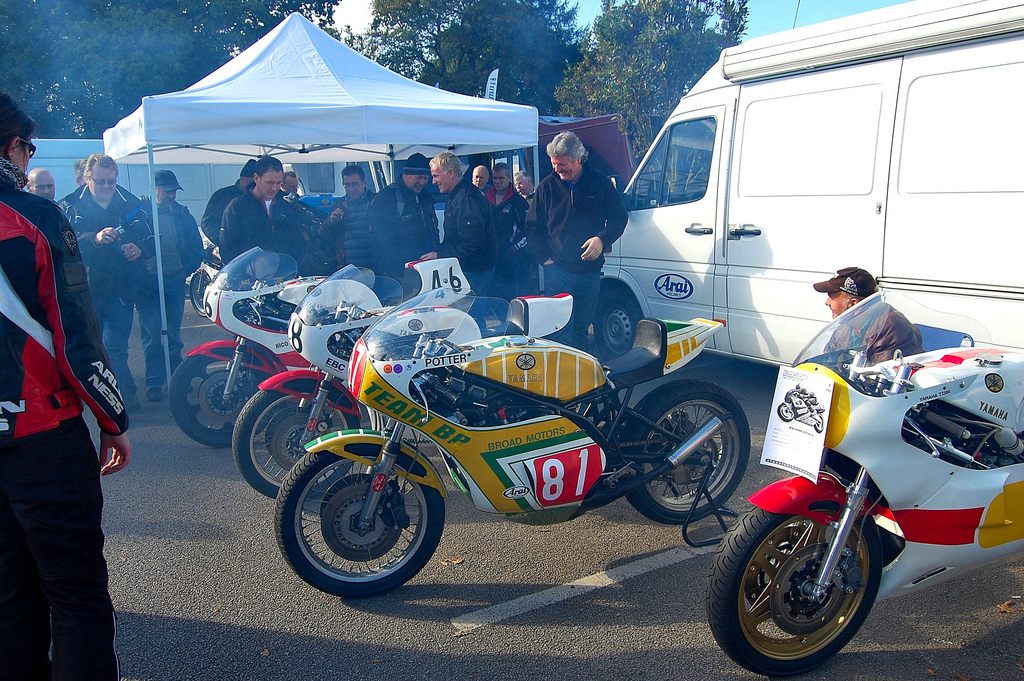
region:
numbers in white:
[541, 454, 595, 500]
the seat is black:
[616, 324, 655, 376]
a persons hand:
[88, 425, 139, 476]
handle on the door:
[685, 222, 709, 242]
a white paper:
[768, 371, 826, 471]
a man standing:
[423, 153, 488, 246]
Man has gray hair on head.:
[541, 127, 587, 167]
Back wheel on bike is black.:
[629, 376, 744, 514]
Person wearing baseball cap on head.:
[814, 265, 873, 308]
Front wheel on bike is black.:
[710, 492, 876, 664]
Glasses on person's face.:
[5, 135, 44, 158]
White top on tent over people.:
[106, 75, 559, 153]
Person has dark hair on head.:
[245, 151, 302, 196]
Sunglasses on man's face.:
[91, 171, 127, 192]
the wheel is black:
[664, 478, 893, 669]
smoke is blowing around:
[4, 7, 593, 355]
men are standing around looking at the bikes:
[19, 65, 623, 340]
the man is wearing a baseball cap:
[735, 188, 895, 334]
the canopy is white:
[64, 0, 571, 289]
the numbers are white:
[495, 424, 620, 542]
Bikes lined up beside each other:
[166, 227, 755, 585]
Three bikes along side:
[152, 233, 763, 588]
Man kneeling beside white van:
[783, 214, 926, 382]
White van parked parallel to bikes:
[578, 29, 1022, 339]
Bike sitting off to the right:
[706, 349, 1016, 654]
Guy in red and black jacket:
[1, 93, 135, 651]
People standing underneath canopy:
[49, 125, 634, 337]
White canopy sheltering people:
[74, 40, 577, 208]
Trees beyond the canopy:
[5, 8, 682, 119]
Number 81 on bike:
[512, 442, 643, 523]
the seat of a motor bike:
[586, 322, 664, 387]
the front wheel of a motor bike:
[264, 445, 433, 583]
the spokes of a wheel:
[320, 545, 368, 581]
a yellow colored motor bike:
[295, 283, 749, 558]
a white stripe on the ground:
[506, 542, 636, 637]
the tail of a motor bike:
[665, 306, 736, 371]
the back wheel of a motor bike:
[623, 384, 775, 533]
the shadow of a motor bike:
[408, 559, 514, 640]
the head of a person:
[8, 100, 56, 186]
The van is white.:
[678, 83, 1021, 321]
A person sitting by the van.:
[797, 268, 925, 382]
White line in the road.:
[436, 559, 708, 617]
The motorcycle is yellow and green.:
[302, 354, 749, 586]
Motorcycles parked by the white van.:
[230, 279, 904, 672]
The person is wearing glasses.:
[10, 139, 46, 166]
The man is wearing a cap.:
[397, 156, 432, 176]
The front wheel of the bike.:
[261, 434, 448, 602]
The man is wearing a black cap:
[806, 276, 915, 300]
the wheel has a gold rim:
[716, 509, 868, 668]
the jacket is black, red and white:
[0, 174, 124, 443]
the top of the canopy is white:
[106, 15, 539, 148]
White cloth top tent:
[100, 10, 559, 431]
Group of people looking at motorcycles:
[2, 86, 753, 678]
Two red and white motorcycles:
[168, 244, 576, 502]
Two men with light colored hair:
[420, 129, 629, 348]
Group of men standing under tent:
[101, 7, 544, 426]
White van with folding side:
[588, 3, 1022, 416]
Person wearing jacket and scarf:
[6, 83, 140, 673]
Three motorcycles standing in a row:
[163, 247, 755, 599]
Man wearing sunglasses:
[62, 151, 158, 415]